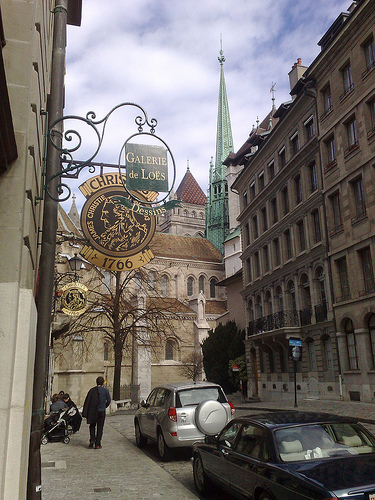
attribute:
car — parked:
[121, 378, 239, 454]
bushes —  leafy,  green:
[204, 329, 244, 392]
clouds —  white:
[105, 29, 201, 94]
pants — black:
[84, 414, 112, 447]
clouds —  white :
[56, 0, 356, 215]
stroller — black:
[40, 413, 74, 449]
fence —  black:
[246, 314, 303, 327]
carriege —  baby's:
[37, 406, 84, 447]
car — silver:
[128, 378, 236, 458]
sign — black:
[102, 117, 207, 210]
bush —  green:
[202, 320, 243, 395]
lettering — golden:
[126, 148, 168, 182]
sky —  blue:
[64, 3, 340, 168]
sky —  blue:
[78, 9, 292, 178]